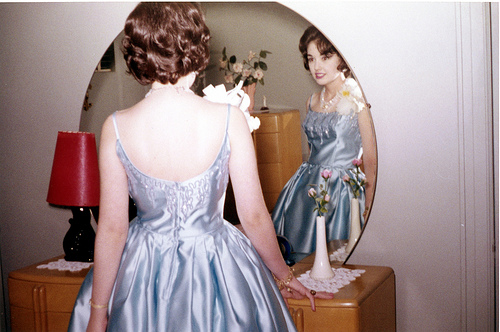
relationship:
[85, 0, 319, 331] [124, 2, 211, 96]
woman has head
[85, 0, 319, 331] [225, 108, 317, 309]
woman has arm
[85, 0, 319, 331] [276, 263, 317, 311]
woman has hand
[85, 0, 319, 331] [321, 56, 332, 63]
woman has eye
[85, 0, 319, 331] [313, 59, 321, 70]
woman has nose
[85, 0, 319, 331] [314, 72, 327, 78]
woman has mouth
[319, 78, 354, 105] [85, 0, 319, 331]
necklace on woman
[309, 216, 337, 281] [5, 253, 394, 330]
vase on top of dresser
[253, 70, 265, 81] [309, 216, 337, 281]
flower inside of vase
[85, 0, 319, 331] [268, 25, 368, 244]
woman has image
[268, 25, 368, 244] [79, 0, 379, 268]
image inside of mirror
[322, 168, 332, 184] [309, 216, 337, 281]
flower inside of vase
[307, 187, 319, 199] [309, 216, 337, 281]
flower inside of vase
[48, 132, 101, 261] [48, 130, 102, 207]
lamp has lamp shade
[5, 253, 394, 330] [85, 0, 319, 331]
dresser in front of woman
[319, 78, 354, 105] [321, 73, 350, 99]
necklace around neck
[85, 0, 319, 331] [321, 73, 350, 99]
woman has neck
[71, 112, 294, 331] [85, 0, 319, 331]
dress on woman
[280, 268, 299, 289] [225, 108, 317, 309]
bracelet around arm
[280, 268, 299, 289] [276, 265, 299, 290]
bracelet around wrist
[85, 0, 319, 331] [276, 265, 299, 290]
woman has wrist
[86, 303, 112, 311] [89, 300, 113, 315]
ribbon around wrist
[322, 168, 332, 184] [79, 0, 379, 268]
flower inside of mirror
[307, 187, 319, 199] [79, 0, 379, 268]
flower inside of mirror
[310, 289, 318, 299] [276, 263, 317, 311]
ring on hand